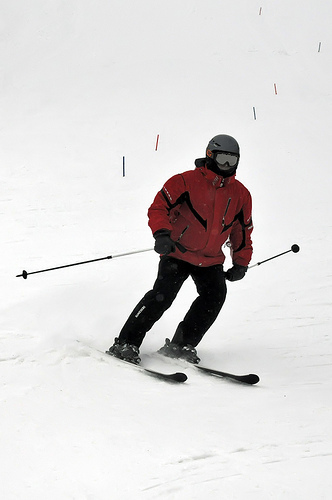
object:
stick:
[121, 155, 125, 178]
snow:
[1, 4, 93, 179]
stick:
[252, 107, 257, 120]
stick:
[317, 39, 323, 57]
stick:
[153, 132, 161, 151]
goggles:
[213, 152, 241, 168]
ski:
[141, 361, 259, 384]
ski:
[56, 336, 188, 382]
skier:
[109, 135, 253, 363]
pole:
[15, 245, 154, 278]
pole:
[247, 244, 299, 270]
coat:
[147, 164, 253, 266]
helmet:
[205, 134, 243, 159]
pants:
[116, 254, 227, 347]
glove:
[153, 228, 176, 254]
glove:
[225, 263, 248, 281]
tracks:
[0, 330, 109, 364]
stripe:
[166, 189, 205, 228]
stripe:
[222, 209, 246, 250]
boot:
[106, 337, 140, 363]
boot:
[158, 336, 200, 364]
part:
[20, 26, 103, 127]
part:
[111, 341, 121, 357]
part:
[227, 367, 258, 386]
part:
[200, 187, 230, 225]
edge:
[202, 366, 243, 374]